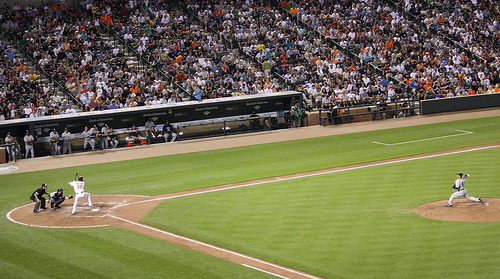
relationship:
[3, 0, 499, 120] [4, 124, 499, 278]
crowd near field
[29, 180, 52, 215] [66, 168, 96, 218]
umpire behind baseball player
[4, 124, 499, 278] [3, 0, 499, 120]
field below crowd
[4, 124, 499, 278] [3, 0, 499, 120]
field under crowd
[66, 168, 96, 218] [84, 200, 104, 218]
baseball player standing at homeplate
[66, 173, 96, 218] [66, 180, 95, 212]
baseball player wearing a uniform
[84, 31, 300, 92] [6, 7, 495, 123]
spectators sitting in stands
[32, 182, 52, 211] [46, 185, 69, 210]
umpire standing behind catcher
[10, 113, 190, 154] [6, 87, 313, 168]
players sitting in dugout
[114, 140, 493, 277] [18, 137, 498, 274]
lines in dirt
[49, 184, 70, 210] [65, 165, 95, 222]
catcher behind batter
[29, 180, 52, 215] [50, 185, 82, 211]
umpire behind catcher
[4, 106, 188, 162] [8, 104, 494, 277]
players watching game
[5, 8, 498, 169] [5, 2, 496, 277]
people in stadium